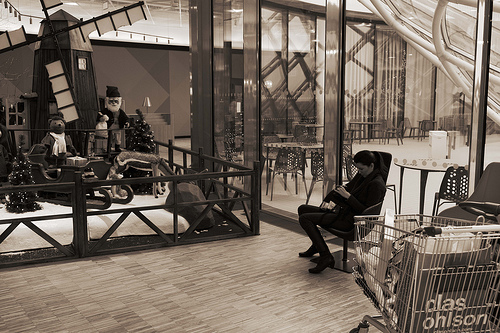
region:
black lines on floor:
[71, 271, 206, 311]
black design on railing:
[94, 205, 184, 268]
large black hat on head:
[98, 78, 123, 104]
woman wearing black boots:
[293, 231, 344, 293]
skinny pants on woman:
[280, 196, 370, 248]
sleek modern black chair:
[313, 136, 409, 250]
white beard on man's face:
[103, 102, 137, 116]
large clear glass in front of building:
[255, 5, 332, 147]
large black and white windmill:
[83, 6, 170, 43]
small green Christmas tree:
[6, 143, 52, 211]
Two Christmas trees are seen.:
[5, 107, 161, 208]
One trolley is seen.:
[346, 211, 491, 312]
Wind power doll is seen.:
[0, 11, 105, 106]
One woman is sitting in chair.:
[310, 150, 395, 265]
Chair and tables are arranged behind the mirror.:
[220, 80, 441, 186]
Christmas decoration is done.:
[5, 26, 245, 256]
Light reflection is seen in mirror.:
[200, 10, 450, 200]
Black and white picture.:
[20, 0, 490, 315]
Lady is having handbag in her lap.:
[316, 180, 357, 230]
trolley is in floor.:
[333, 239, 471, 331]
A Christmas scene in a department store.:
[5, 0, 255, 250]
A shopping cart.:
[350, 190, 495, 325]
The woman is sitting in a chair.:
[282, 135, 387, 275]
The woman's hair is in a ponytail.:
[345, 145, 395, 180]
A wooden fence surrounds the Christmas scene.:
[30, 135, 265, 255]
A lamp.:
[135, 90, 158, 114]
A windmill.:
[5, 0, 146, 140]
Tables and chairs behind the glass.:
[250, 117, 327, 202]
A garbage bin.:
[425, 120, 455, 160]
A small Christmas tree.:
[5, 141, 40, 232]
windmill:
[0, 1, 149, 197]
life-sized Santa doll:
[95, 78, 133, 183]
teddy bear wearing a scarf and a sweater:
[32, 100, 77, 180]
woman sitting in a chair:
[280, 141, 417, 281]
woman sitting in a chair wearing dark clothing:
[276, 146, 412, 288]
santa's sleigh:
[0, 149, 149, 210]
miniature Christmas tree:
[5, 145, 49, 230]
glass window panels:
[185, 7, 492, 232]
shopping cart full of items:
[355, 202, 495, 330]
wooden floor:
[197, 249, 344, 320]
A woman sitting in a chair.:
[279, 134, 399, 274]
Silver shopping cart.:
[344, 199, 498, 328]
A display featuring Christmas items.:
[2, 0, 223, 213]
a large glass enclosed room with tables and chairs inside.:
[202, 28, 498, 241]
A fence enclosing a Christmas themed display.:
[19, 129, 262, 249]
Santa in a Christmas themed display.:
[98, 76, 148, 126]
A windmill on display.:
[20, 0, 148, 169]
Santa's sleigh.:
[14, 144, 139, 210]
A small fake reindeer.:
[103, 141, 191, 211]